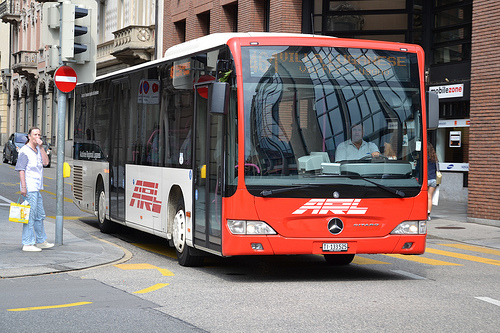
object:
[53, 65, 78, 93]
street sign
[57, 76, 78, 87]
red and white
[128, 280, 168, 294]
yellow markings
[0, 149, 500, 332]
street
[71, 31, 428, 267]
bus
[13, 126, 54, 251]
person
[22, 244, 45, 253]
tennis shoe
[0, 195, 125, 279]
sidewalk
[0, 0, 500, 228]
brick building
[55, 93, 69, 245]
gray pole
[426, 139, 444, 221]
person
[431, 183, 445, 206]
white bag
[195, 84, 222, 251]
door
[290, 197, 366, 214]
logo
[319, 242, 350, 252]
license plate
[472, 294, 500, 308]
white lines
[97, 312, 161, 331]
dark grey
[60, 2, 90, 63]
traffic light